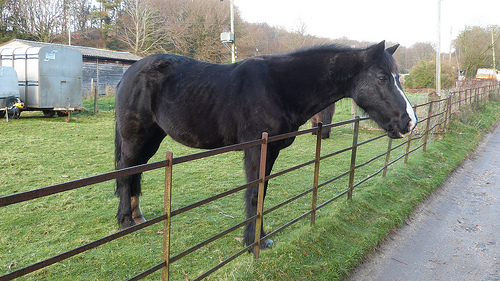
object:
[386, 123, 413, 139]
mouth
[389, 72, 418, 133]
patch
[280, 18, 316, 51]
trees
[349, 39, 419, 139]
head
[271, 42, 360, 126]
neck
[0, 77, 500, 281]
fence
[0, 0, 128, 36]
sky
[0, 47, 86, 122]
trailer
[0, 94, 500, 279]
field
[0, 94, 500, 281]
grass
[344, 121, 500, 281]
pavement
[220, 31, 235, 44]
metal box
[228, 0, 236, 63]
pole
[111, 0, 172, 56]
trees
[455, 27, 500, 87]
tree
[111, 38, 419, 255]
horse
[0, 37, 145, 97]
building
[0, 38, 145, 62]
roof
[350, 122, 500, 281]
floor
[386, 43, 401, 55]
ear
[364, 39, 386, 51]
ear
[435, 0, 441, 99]
pole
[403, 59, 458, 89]
bush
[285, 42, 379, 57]
mane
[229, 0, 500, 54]
skies